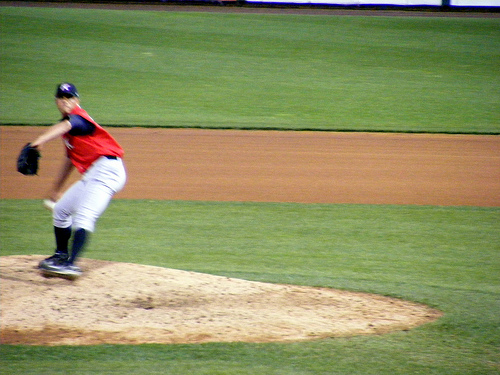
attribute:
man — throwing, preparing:
[18, 83, 126, 280]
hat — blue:
[56, 83, 78, 98]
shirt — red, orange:
[59, 108, 123, 173]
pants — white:
[51, 155, 127, 232]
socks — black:
[52, 226, 92, 262]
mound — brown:
[0, 254, 283, 339]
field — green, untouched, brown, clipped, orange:
[119, 9, 500, 373]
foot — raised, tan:
[46, 262, 80, 279]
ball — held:
[46, 197, 56, 212]